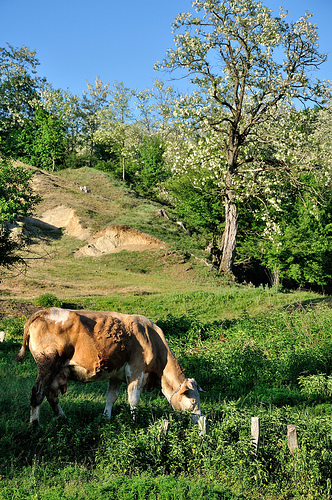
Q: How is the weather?
A: It is clear.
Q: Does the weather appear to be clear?
A: Yes, it is clear.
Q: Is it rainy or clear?
A: It is clear.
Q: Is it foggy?
A: No, it is clear.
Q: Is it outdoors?
A: Yes, it is outdoors.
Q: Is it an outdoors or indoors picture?
A: It is outdoors.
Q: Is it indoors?
A: No, it is outdoors.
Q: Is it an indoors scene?
A: No, it is outdoors.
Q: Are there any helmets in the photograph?
A: No, there are no helmets.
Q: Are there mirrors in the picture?
A: No, there are no mirrors.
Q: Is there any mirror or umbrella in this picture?
A: No, there are no mirrors or umbrellas.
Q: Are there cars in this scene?
A: No, there are no cars.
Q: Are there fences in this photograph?
A: Yes, there is a fence.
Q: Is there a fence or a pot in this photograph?
A: Yes, there is a fence.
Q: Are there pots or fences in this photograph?
A: Yes, there is a fence.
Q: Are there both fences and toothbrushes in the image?
A: No, there is a fence but no toothbrushes.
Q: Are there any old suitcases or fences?
A: Yes, there is an old fence.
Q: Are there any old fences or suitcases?
A: Yes, there is an old fence.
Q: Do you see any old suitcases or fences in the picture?
A: Yes, there is an old fence.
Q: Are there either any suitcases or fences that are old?
A: Yes, the fence is old.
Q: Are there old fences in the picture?
A: Yes, there is an old fence.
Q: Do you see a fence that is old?
A: Yes, there is a fence that is old.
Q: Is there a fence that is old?
A: Yes, there is a fence that is old.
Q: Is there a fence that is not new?
A: Yes, there is a old fence.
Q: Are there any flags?
A: No, there are no flags.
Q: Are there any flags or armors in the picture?
A: No, there are no flags or armors.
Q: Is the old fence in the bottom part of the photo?
A: Yes, the fence is in the bottom of the image.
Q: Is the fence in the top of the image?
A: No, the fence is in the bottom of the image.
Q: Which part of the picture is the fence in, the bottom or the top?
A: The fence is in the bottom of the image.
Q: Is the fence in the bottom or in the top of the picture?
A: The fence is in the bottom of the image.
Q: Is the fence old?
A: Yes, the fence is old.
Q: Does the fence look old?
A: Yes, the fence is old.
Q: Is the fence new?
A: No, the fence is old.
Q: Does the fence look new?
A: No, the fence is old.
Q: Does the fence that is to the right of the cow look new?
A: No, the fence is old.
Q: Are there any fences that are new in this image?
A: No, there is a fence but it is old.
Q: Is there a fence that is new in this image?
A: No, there is a fence but it is old.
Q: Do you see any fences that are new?
A: No, there is a fence but it is old.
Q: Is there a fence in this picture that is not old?
A: No, there is a fence but it is old.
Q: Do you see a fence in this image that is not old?
A: No, there is a fence but it is old.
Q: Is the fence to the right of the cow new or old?
A: The fence is old.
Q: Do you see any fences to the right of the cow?
A: Yes, there is a fence to the right of the cow.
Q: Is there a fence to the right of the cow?
A: Yes, there is a fence to the right of the cow.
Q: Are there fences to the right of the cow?
A: Yes, there is a fence to the right of the cow.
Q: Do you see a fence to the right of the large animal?
A: Yes, there is a fence to the right of the cow.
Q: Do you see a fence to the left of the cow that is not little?
A: No, the fence is to the right of the cow.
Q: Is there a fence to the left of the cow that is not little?
A: No, the fence is to the right of the cow.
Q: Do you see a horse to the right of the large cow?
A: No, there is a fence to the right of the cow.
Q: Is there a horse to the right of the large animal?
A: No, there is a fence to the right of the cow.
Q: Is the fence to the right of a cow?
A: Yes, the fence is to the right of a cow.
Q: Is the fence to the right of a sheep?
A: No, the fence is to the right of a cow.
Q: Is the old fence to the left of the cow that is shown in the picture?
A: No, the fence is to the right of the cow.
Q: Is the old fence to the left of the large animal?
A: No, the fence is to the right of the cow.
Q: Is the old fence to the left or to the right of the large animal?
A: The fence is to the right of the cow.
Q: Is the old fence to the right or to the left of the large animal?
A: The fence is to the right of the cow.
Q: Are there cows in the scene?
A: Yes, there is a cow.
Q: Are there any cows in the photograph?
A: Yes, there is a cow.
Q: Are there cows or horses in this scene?
A: Yes, there is a cow.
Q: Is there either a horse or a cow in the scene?
A: Yes, there is a cow.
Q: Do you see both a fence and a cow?
A: Yes, there are both a cow and a fence.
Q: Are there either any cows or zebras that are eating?
A: Yes, the cow is eating.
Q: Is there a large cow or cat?
A: Yes, there is a large cow.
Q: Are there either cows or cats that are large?
A: Yes, the cow is large.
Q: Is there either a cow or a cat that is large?
A: Yes, the cow is large.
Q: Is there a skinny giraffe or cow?
A: Yes, there is a skinny cow.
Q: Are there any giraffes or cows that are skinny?
A: Yes, the cow is skinny.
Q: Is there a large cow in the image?
A: Yes, there is a large cow.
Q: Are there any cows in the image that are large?
A: Yes, there is a cow that is large.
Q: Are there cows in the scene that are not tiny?
A: Yes, there is a large cow.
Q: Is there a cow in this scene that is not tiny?
A: Yes, there is a large cow.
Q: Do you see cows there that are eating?
A: Yes, there is a cow that is eating.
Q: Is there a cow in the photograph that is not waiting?
A: Yes, there is a cow that is eating.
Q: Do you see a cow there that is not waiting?
A: Yes, there is a cow that is eating .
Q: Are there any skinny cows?
A: Yes, there is a skinny cow.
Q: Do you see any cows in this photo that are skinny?
A: Yes, there is a cow that is skinny.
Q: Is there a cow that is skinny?
A: Yes, there is a cow that is skinny.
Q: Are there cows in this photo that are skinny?
A: Yes, there is a cow that is skinny.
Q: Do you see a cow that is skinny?
A: Yes, there is a cow that is skinny.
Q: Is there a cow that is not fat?
A: Yes, there is a skinny cow.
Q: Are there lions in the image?
A: No, there are no lions.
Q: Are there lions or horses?
A: No, there are no lions or horses.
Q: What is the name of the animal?
A: The animal is a cow.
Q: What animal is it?
A: The animal is a cow.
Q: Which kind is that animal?
A: This is a cow.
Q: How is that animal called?
A: This is a cow.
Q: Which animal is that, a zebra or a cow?
A: This is a cow.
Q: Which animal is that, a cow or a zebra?
A: This is a cow.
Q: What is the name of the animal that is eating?
A: The animal is a cow.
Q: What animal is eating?
A: The animal is a cow.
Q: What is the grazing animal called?
A: The animal is a cow.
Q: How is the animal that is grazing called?
A: The animal is a cow.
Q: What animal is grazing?
A: The animal is a cow.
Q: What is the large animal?
A: The animal is a cow.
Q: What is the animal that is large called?
A: The animal is a cow.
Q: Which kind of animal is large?
A: The animal is a cow.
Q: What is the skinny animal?
A: The animal is a cow.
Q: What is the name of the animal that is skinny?
A: The animal is a cow.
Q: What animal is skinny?
A: The animal is a cow.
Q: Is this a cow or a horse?
A: This is a cow.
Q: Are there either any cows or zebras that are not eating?
A: No, there is a cow but it is eating.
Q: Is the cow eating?
A: Yes, the cow is eating.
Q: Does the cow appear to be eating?
A: Yes, the cow is eating.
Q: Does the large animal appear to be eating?
A: Yes, the cow is eating.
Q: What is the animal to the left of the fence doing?
A: The cow is eating.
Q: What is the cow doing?
A: The cow is eating.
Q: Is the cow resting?
A: No, the cow is eating.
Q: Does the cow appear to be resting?
A: No, the cow is eating.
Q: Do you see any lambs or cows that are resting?
A: No, there is a cow but it is eating.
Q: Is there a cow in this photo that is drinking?
A: No, there is a cow but it is eating.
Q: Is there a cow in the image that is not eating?
A: No, there is a cow but it is eating.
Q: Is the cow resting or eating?
A: The cow is eating.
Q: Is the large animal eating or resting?
A: The cow is eating.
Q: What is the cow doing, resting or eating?
A: The cow is eating.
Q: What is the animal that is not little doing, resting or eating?
A: The cow is eating.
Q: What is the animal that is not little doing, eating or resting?
A: The cow is eating.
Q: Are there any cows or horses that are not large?
A: No, there is a cow but it is large.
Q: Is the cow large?
A: Yes, the cow is large.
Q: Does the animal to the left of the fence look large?
A: Yes, the cow is large.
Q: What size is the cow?
A: The cow is large.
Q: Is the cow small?
A: No, the cow is large.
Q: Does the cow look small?
A: No, the cow is large.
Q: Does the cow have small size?
A: No, the cow is large.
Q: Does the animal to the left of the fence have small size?
A: No, the cow is large.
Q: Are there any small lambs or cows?
A: No, there is a cow but it is large.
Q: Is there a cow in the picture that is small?
A: No, there is a cow but it is large.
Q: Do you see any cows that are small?
A: No, there is a cow but it is large.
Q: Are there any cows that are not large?
A: No, there is a cow but it is large.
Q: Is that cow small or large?
A: The cow is large.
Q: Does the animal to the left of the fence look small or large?
A: The cow is large.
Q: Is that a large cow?
A: Yes, that is a large cow.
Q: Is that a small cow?
A: No, that is a large cow.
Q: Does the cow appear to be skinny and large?
A: Yes, the cow is skinny and large.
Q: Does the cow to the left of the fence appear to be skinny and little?
A: No, the cow is skinny but large.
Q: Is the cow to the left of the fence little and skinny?
A: No, the cow is skinny but large.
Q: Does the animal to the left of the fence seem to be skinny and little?
A: No, the cow is skinny but large.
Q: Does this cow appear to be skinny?
A: Yes, the cow is skinny.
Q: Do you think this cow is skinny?
A: Yes, the cow is skinny.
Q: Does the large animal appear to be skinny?
A: Yes, the cow is skinny.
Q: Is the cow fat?
A: No, the cow is skinny.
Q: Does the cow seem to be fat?
A: No, the cow is skinny.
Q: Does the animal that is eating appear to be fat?
A: No, the cow is skinny.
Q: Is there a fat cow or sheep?
A: No, there is a cow but it is skinny.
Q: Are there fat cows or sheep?
A: No, there is a cow but it is skinny.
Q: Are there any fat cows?
A: No, there is a cow but it is skinny.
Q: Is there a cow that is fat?
A: No, there is a cow but it is skinny.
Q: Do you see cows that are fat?
A: No, there is a cow but it is skinny.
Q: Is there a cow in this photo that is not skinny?
A: No, there is a cow but it is skinny.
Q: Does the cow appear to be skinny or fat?
A: The cow is skinny.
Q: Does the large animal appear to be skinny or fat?
A: The cow is skinny.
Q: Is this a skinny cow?
A: Yes, this is a skinny cow.